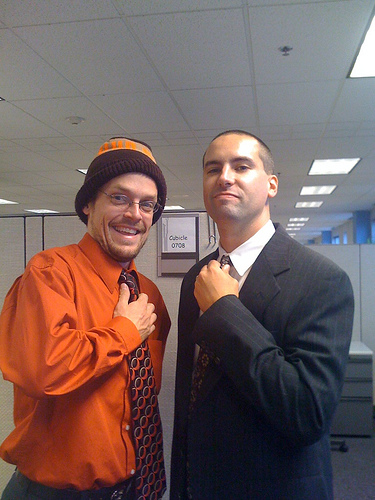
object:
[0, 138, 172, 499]
man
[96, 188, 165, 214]
glasses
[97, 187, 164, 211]
frame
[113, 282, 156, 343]
hand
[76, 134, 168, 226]
knit hat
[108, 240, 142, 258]
chin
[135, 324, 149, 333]
veins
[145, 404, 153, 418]
circles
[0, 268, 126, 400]
arm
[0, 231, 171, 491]
shirt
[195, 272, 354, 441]
sleeve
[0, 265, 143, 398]
sleeve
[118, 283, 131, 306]
fingers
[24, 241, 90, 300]
shoulder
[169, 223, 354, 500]
jacket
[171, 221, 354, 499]
suit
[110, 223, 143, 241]
smile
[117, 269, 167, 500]
tie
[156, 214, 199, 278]
sign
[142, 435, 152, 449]
circle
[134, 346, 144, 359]
circle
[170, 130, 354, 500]
business man